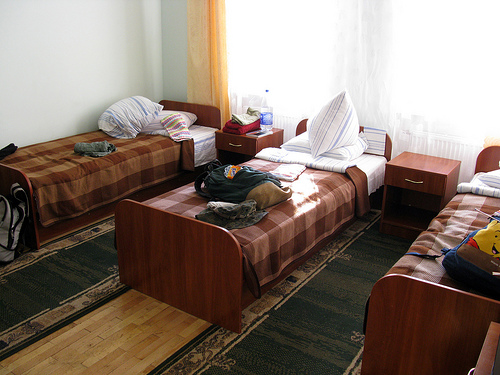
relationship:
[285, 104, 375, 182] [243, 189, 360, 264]
pillows on bed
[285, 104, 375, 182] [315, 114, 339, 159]
pillows has stripes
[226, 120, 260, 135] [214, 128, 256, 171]
towel on side table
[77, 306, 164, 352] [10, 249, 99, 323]
floor has carpet